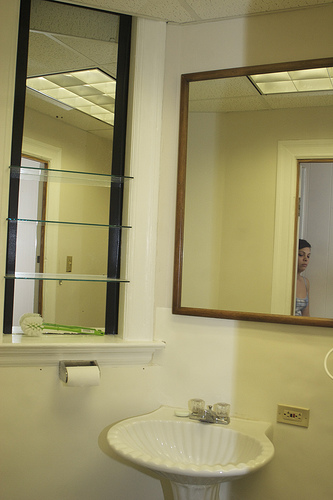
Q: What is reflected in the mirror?
A: A woman.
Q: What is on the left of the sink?
A: A bar of soap.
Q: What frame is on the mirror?
A: A wooden frame.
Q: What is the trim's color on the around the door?
A: White.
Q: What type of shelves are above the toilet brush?
A: Glass.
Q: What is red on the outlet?
A: The reset button.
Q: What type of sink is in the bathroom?
A: A pedestal sink.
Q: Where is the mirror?
A: Above the sink.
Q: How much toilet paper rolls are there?
A: One.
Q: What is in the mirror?
A: Reflection.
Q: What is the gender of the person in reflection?
A: Female.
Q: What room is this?
A: Bathroom.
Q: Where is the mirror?
A: Wall.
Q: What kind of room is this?
A: Bathroom.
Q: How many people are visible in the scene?
A: One.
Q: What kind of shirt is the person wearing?
A: Tank top.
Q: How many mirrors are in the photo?
A: Two.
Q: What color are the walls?
A: White.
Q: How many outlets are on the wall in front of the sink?
A: One.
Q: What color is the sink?
A: White.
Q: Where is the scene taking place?
A: In a bathroom.